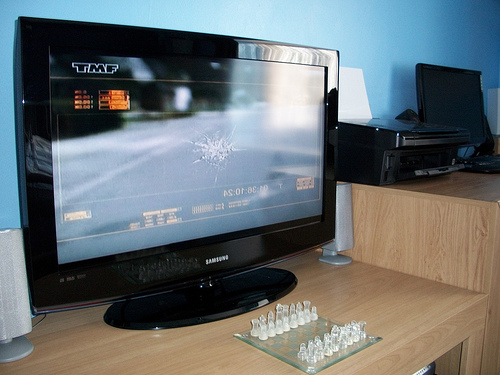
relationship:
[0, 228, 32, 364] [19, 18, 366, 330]
gray speaker by tv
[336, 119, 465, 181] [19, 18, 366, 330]
computer printer by tv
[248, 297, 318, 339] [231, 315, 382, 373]
pieces by board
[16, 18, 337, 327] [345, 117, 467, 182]
computer monitor by printer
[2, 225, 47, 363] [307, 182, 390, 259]
gray speaker on desk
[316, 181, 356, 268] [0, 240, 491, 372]
speaker on desk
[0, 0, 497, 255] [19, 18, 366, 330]
wall behind tv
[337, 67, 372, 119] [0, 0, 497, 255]
paper by wall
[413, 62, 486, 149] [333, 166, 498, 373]
computer monitor on desk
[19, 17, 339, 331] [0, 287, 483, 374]
tv on table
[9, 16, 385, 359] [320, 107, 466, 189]
computer for printer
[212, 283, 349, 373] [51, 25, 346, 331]
chess in front of monitor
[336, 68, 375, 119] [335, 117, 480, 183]
paper fed into printer